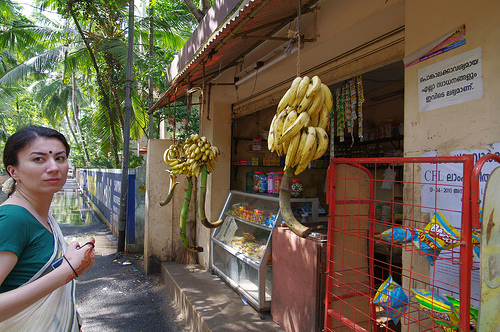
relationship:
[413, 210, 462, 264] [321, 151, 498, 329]
chips on red shelf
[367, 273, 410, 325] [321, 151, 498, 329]
chips on red shelf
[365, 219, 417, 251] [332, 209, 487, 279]
chips on rack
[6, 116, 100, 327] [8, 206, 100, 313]
woman wearing shirt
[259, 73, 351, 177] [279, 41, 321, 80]
bananas hanging from string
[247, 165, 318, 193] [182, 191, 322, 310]
items on counter